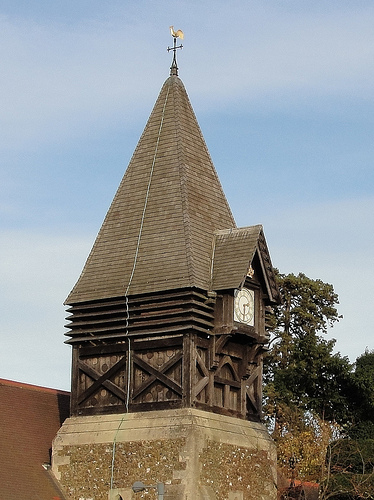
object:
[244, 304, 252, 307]
dials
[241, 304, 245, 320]
dials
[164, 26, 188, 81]
tower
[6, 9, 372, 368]
sky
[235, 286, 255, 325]
clockface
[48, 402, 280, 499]
base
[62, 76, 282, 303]
roof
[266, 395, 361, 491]
leaves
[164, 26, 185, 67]
cross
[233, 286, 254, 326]
clock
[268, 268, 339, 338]
tree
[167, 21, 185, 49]
rooster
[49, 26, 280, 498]
building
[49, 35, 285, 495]
spire